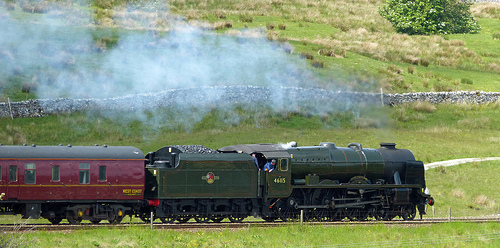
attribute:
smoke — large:
[9, 10, 381, 125]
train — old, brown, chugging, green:
[5, 133, 436, 225]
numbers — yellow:
[270, 174, 289, 185]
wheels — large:
[304, 183, 416, 219]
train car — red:
[1, 139, 151, 223]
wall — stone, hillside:
[4, 84, 497, 106]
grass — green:
[16, 44, 493, 87]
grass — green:
[9, 5, 487, 44]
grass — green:
[8, 224, 500, 246]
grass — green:
[427, 68, 445, 79]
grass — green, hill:
[298, 18, 331, 34]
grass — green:
[419, 137, 442, 154]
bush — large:
[382, 0, 477, 35]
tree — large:
[381, 2, 474, 37]